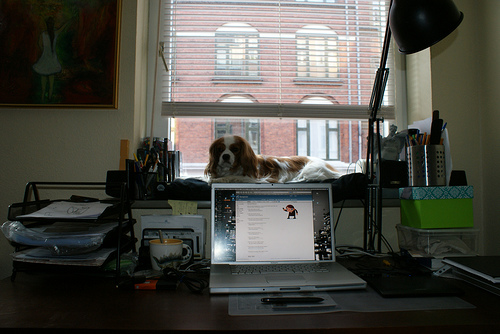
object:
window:
[214, 22, 259, 75]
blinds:
[155, 0, 396, 120]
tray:
[8, 194, 130, 226]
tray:
[3, 213, 138, 253]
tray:
[6, 235, 139, 289]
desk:
[1, 239, 499, 332]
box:
[397, 183, 475, 230]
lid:
[396, 182, 476, 201]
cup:
[148, 237, 192, 269]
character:
[282, 204, 298, 219]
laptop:
[206, 178, 366, 292]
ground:
[340, 50, 417, 125]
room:
[0, 0, 500, 331]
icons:
[211, 189, 234, 265]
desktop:
[209, 183, 337, 265]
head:
[204, 133, 257, 175]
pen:
[260, 296, 323, 302]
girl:
[33, 12, 64, 103]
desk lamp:
[335, 0, 464, 296]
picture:
[2, 1, 120, 112]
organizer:
[0, 194, 136, 296]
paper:
[282, 291, 338, 309]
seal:
[174, 172, 363, 182]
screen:
[215, 187, 334, 262]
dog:
[199, 136, 339, 184]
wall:
[3, 1, 151, 208]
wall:
[394, 0, 497, 256]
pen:
[159, 229, 166, 243]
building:
[162, 0, 381, 165]